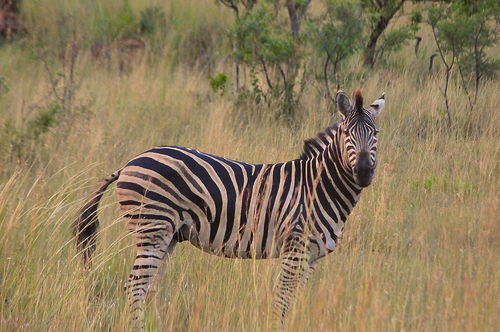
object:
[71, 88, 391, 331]
zebra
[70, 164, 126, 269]
tail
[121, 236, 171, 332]
back legs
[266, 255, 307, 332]
front legs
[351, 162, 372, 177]
nose and nostrils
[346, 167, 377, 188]
mouth area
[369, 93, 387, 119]
left ear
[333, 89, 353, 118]
right ear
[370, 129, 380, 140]
left eye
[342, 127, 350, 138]
right eye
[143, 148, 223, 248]
stripes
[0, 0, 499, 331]
plain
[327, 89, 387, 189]
head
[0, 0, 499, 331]
grass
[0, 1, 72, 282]
back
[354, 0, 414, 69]
tree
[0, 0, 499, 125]
bushes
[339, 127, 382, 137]
two eyes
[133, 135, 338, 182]
backside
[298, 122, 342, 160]
mane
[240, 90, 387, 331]
front half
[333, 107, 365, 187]
sideview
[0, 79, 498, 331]
foreground